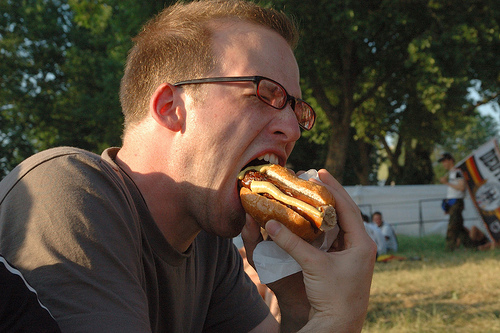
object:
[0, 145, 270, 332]
shirt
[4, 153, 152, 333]
sleeve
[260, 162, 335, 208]
bread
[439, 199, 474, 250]
trouser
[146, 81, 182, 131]
ear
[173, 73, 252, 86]
fram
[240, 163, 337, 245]
hot dog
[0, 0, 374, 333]
man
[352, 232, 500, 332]
grass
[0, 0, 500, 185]
tree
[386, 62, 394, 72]
leaves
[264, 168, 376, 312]
hand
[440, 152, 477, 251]
man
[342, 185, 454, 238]
wall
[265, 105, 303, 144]
nose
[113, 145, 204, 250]
neck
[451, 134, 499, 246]
flag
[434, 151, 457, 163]
cap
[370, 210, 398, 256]
people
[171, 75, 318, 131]
eyeglasses